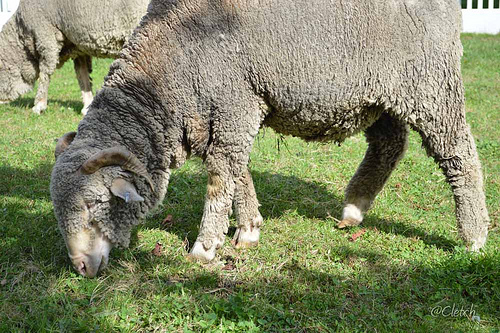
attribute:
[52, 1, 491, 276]
sheep — eating, watching, male, female, enjoying, grazing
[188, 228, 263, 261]
hoof — white, grey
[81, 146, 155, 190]
horn — curved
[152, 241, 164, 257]
leaf — brown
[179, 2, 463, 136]
body — grey, furry